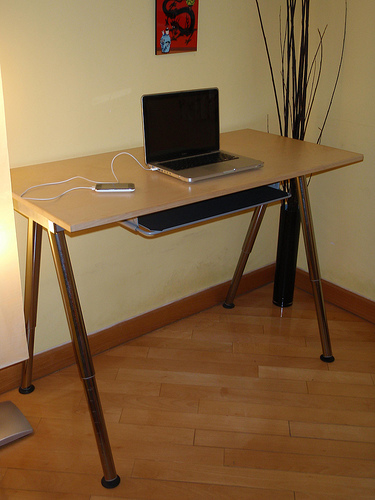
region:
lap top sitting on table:
[99, 84, 247, 195]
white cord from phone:
[35, 167, 89, 217]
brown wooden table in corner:
[292, 131, 346, 166]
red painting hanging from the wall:
[145, 1, 212, 57]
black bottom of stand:
[97, 471, 131, 487]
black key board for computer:
[142, 188, 288, 236]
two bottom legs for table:
[217, 174, 334, 363]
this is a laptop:
[92, 69, 290, 212]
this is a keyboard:
[103, 161, 327, 283]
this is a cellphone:
[90, 151, 151, 213]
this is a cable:
[9, 140, 178, 221]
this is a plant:
[246, 1, 360, 217]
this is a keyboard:
[157, 145, 236, 176]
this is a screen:
[140, 83, 233, 170]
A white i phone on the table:
[95, 175, 141, 194]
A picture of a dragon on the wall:
[155, 2, 202, 53]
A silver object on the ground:
[3, 398, 37, 444]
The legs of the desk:
[34, 228, 338, 487]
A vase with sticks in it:
[250, 7, 305, 307]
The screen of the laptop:
[142, 95, 233, 155]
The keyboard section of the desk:
[122, 187, 287, 243]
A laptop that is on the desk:
[138, 92, 262, 178]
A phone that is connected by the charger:
[15, 152, 171, 217]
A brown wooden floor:
[1, 281, 372, 497]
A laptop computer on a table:
[12, 82, 367, 233]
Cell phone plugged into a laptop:
[14, 83, 266, 208]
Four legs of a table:
[15, 175, 337, 492]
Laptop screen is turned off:
[136, 82, 221, 165]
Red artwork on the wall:
[150, 0, 203, 58]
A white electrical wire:
[17, 149, 160, 204]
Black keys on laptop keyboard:
[158, 148, 240, 178]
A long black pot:
[267, 179, 305, 311]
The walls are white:
[1, 4, 372, 371]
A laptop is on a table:
[11, 87, 365, 233]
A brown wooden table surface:
[9, 126, 367, 233]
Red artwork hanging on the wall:
[147, 2, 204, 60]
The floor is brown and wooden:
[2, 278, 371, 497]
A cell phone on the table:
[87, 173, 140, 199]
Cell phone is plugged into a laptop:
[17, 85, 270, 205]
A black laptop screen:
[135, 84, 226, 166]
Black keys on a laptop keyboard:
[151, 148, 243, 175]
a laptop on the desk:
[84, 79, 268, 218]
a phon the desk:
[77, 145, 153, 209]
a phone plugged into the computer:
[52, 135, 305, 228]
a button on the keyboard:
[173, 164, 185, 170]